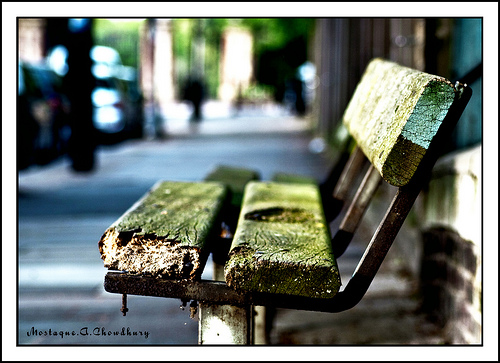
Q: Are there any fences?
A: No, there are no fences.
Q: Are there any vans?
A: No, there are no vans.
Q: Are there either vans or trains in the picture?
A: No, there are no vans or trains.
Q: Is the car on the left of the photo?
A: Yes, the car is on the left of the image.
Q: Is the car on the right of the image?
A: No, the car is on the left of the image.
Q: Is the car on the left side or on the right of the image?
A: The car is on the left of the image.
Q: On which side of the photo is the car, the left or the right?
A: The car is on the left of the image.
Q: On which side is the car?
A: The car is on the left of the image.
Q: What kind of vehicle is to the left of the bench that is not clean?
A: The vehicle is a car.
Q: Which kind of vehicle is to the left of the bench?
A: The vehicle is a car.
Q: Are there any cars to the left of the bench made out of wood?
A: Yes, there is a car to the left of the bench.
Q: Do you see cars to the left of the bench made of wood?
A: Yes, there is a car to the left of the bench.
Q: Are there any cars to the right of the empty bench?
A: No, the car is to the left of the bench.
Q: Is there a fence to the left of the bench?
A: No, there is a car to the left of the bench.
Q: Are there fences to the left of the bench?
A: No, there is a car to the left of the bench.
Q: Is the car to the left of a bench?
A: Yes, the car is to the left of a bench.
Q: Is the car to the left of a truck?
A: No, the car is to the left of a bench.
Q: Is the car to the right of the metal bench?
A: No, the car is to the left of the bench.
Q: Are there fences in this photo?
A: No, there are no fences.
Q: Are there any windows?
A: Yes, there is a window.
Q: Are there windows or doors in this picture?
A: Yes, there is a window.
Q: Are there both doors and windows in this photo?
A: No, there is a window but no doors.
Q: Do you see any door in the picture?
A: No, there are no doors.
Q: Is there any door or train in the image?
A: No, there are no doors or trains.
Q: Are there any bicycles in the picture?
A: No, there are no bicycles.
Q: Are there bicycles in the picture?
A: No, there are no bicycles.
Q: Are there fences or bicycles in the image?
A: No, there are no bicycles or fences.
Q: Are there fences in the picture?
A: No, there are no fences.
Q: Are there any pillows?
A: No, there are no pillows.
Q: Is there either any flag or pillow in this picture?
A: No, there are no pillows or flags.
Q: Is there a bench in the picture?
A: Yes, there is a bench.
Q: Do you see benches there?
A: Yes, there is a bench.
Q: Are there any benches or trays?
A: Yes, there is a bench.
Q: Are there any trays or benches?
A: Yes, there is a bench.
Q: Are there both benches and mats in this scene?
A: No, there is a bench but no mats.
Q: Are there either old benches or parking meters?
A: Yes, there is an old bench.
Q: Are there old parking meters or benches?
A: Yes, there is an old bench.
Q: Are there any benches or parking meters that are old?
A: Yes, the bench is old.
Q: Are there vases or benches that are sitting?
A: Yes, the bench is sitting.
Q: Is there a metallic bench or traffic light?
A: Yes, there is a metal bench.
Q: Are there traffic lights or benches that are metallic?
A: Yes, the bench is metallic.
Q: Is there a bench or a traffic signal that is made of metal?
A: Yes, the bench is made of metal.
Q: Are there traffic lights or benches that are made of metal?
A: Yes, the bench is made of metal.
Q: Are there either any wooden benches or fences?
A: Yes, there is a wood bench.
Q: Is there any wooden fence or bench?
A: Yes, there is a wood bench.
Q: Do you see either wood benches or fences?
A: Yes, there is a wood bench.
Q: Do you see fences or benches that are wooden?
A: Yes, the bench is wooden.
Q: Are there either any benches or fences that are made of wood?
A: Yes, the bench is made of wood.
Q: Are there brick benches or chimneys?
A: Yes, there is a brick bench.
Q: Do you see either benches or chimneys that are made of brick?
A: Yes, the bench is made of brick.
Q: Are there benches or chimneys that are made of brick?
A: Yes, the bench is made of brick.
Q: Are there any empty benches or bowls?
A: Yes, there is an empty bench.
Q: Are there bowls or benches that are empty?
A: Yes, the bench is empty.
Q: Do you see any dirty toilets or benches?
A: Yes, there is a dirty bench.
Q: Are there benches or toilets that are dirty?
A: Yes, the bench is dirty.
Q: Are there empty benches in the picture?
A: Yes, there is an empty bench.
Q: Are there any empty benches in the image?
A: Yes, there is an empty bench.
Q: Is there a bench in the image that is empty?
A: Yes, there is a bench that is empty.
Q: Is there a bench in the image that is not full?
A: Yes, there is a empty bench.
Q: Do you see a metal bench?
A: Yes, there is a bench that is made of metal.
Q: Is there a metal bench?
A: Yes, there is a bench that is made of metal.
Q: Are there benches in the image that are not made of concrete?
A: Yes, there is a bench that is made of metal.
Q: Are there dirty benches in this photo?
A: Yes, there is a dirty bench.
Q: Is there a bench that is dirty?
A: Yes, there is a bench that is dirty.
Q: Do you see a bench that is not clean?
A: Yes, there is a dirty bench.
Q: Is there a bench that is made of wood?
A: Yes, there is a bench that is made of wood.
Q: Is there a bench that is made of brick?
A: Yes, there is a bench that is made of brick.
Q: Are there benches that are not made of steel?
A: Yes, there is a bench that is made of brick.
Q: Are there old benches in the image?
A: Yes, there is an old bench.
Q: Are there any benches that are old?
A: Yes, there is a bench that is old.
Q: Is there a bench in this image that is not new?
A: Yes, there is a old bench.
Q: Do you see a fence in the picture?
A: No, there are no fences.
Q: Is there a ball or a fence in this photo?
A: No, there are no fences or balls.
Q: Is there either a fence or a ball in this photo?
A: No, there are no fences or balls.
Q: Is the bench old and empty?
A: Yes, the bench is old and empty.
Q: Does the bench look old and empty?
A: Yes, the bench is old and empty.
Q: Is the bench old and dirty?
A: Yes, the bench is old and dirty.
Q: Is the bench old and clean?
A: No, the bench is old but dirty.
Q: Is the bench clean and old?
A: No, the bench is old but dirty.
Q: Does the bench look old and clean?
A: No, the bench is old but dirty.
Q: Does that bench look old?
A: Yes, the bench is old.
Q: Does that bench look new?
A: No, the bench is old.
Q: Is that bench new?
A: No, the bench is old.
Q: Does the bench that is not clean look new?
A: No, the bench is old.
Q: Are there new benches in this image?
A: No, there is a bench but it is old.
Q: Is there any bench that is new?
A: No, there is a bench but it is old.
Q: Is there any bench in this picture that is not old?
A: No, there is a bench but it is old.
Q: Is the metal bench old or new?
A: The bench is old.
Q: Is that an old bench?
A: Yes, that is an old bench.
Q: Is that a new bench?
A: No, that is an old bench.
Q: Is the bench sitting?
A: Yes, the bench is sitting.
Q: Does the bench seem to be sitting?
A: Yes, the bench is sitting.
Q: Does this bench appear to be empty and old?
A: Yes, the bench is empty and old.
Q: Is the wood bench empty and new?
A: No, the bench is empty but old.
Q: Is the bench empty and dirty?
A: Yes, the bench is empty and dirty.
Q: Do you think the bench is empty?
A: Yes, the bench is empty.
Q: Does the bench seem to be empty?
A: Yes, the bench is empty.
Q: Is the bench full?
A: No, the bench is empty.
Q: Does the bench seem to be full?
A: No, the bench is empty.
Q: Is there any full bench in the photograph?
A: No, there is a bench but it is empty.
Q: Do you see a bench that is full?
A: No, there is a bench but it is empty.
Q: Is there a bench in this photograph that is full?
A: No, there is a bench but it is empty.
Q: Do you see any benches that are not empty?
A: No, there is a bench but it is empty.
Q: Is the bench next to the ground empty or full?
A: The bench is empty.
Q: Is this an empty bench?
A: Yes, this is an empty bench.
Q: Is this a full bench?
A: No, this is an empty bench.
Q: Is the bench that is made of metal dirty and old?
A: Yes, the bench is dirty and old.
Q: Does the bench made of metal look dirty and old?
A: Yes, the bench is dirty and old.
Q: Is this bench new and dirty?
A: No, the bench is dirty but old.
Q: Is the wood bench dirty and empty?
A: Yes, the bench is dirty and empty.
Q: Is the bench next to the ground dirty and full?
A: No, the bench is dirty but empty.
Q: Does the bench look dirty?
A: Yes, the bench is dirty.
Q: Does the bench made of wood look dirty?
A: Yes, the bench is dirty.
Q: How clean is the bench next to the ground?
A: The bench is dirty.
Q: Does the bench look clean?
A: No, the bench is dirty.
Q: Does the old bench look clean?
A: No, the bench is dirty.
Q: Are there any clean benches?
A: No, there is a bench but it is dirty.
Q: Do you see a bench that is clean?
A: No, there is a bench but it is dirty.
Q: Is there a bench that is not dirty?
A: No, there is a bench but it is dirty.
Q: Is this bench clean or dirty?
A: The bench is dirty.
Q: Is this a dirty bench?
A: Yes, this is a dirty bench.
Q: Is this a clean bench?
A: No, this is a dirty bench.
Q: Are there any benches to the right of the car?
A: Yes, there is a bench to the right of the car.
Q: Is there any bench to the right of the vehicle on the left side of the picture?
A: Yes, there is a bench to the right of the car.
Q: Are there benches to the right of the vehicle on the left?
A: Yes, there is a bench to the right of the car.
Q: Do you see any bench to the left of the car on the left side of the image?
A: No, the bench is to the right of the car.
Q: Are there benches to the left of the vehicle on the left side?
A: No, the bench is to the right of the car.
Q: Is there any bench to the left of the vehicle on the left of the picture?
A: No, the bench is to the right of the car.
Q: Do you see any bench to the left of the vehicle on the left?
A: No, the bench is to the right of the car.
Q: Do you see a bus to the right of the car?
A: No, there is a bench to the right of the car.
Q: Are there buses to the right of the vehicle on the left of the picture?
A: No, there is a bench to the right of the car.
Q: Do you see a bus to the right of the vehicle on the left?
A: No, there is a bench to the right of the car.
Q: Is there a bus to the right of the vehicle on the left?
A: No, there is a bench to the right of the car.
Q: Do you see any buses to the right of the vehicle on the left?
A: No, there is a bench to the right of the car.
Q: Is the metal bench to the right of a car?
A: Yes, the bench is to the right of a car.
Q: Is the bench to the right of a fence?
A: No, the bench is to the right of a car.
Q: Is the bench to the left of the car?
A: No, the bench is to the right of the car.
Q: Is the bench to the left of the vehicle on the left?
A: No, the bench is to the right of the car.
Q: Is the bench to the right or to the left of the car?
A: The bench is to the right of the car.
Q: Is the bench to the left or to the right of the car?
A: The bench is to the right of the car.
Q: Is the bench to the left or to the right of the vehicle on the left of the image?
A: The bench is to the right of the car.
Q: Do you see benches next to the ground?
A: Yes, there is a bench next to the ground.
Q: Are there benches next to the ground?
A: Yes, there is a bench next to the ground.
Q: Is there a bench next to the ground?
A: Yes, there is a bench next to the ground.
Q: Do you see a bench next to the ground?
A: Yes, there is a bench next to the ground.